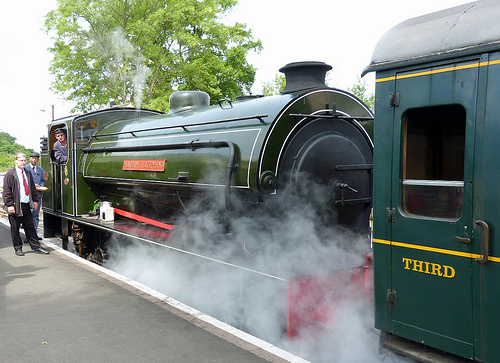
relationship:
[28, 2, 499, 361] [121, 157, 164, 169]
train has sign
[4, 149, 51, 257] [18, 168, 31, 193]
man wears tie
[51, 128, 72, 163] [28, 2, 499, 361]
man driving train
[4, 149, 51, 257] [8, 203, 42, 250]
man wearing black pants